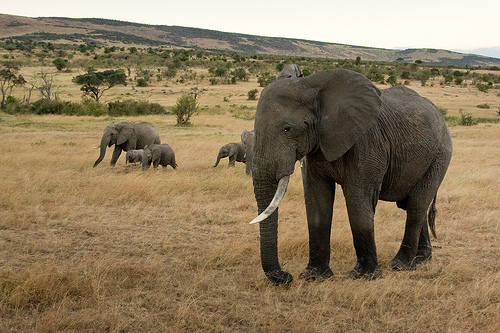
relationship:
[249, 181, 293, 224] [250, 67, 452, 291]
left tusk of elephant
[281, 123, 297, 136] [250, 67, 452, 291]
left eye of elephant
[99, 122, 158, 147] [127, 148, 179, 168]
adult elephant near younger elephants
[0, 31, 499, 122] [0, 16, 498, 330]
trees on savannah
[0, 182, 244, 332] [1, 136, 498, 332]
patch of grass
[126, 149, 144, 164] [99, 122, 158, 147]
baby elephant near adult elephant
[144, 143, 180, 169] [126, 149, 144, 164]
juvenile elephant near baby elephant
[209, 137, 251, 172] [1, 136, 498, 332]
small elephants on grass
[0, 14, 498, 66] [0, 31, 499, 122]
hillside near trees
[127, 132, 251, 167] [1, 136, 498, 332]
small elephants on grass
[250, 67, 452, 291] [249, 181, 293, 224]
elephant has left tusk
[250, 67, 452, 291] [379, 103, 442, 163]
elephant has wrinkles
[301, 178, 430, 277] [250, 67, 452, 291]
four legs of elephant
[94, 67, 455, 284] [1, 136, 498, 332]
six elephants on grass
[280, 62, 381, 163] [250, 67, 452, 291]
ears of elephant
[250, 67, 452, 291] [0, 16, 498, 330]
elephant on savannah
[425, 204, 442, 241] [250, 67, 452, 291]
hair of elephant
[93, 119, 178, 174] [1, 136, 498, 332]
three elphants on grass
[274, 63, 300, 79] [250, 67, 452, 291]
right ear of elephant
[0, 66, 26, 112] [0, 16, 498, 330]
tall tree on savannah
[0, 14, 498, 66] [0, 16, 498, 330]
hillside on savannah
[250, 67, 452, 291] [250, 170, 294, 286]
elephant has trunk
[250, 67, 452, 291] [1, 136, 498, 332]
elephant on grass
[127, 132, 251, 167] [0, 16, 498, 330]
small elephants on savannah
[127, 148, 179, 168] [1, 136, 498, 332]
younger elephants on grass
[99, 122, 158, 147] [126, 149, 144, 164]
adult elephant near baby elephant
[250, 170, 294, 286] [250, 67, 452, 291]
trunk on elephant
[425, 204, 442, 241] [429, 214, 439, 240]
hair has hair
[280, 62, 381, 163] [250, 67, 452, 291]
ears on elephant